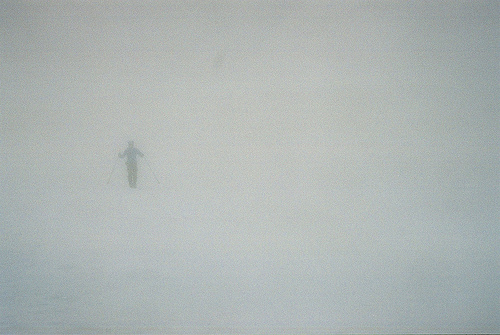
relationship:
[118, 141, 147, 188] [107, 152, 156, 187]
man holding ski poles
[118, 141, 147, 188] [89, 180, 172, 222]
man standing in snow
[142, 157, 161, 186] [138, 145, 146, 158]
pole in hand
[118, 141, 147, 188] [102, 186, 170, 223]
man standing in snow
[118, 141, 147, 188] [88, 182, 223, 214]
man standing in snow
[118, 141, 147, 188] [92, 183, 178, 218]
man standing in snow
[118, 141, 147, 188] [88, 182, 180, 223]
man standing in snow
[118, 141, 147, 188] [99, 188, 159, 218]
man standing in snow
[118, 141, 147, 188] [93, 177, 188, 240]
man standing in snow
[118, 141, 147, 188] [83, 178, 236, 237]
man standing in snow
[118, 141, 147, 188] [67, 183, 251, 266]
man standing in snow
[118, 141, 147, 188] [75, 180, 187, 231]
man on snow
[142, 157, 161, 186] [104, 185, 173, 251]
pole sticking in snow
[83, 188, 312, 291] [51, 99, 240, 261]
snow on ground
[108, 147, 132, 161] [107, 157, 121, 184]
hand holding pole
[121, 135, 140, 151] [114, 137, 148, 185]
head of man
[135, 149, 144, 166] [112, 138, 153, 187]
arm of man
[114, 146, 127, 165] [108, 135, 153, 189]
arm of man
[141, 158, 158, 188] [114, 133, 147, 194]
stick of man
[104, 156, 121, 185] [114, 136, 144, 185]
stick of man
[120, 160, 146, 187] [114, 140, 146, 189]
legs of man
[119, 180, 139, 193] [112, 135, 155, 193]
shoes of man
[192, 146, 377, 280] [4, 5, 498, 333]
patch of snow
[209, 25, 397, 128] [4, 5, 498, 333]
flurry of snow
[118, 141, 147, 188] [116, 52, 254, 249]
man in field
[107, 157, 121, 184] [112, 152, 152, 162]
pole in hand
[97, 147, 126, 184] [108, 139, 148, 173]
pole in hand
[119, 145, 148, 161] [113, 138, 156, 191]
jacket on person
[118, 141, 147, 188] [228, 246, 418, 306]
man through snow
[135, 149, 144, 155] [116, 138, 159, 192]
arm of person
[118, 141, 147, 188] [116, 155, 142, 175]
man wearing outfit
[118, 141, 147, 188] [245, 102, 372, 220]
man standing mist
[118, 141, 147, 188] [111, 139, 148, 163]
man with arms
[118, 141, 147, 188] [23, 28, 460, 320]
man on scene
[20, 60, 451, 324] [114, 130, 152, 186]
picture with person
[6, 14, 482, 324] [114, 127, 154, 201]
image with person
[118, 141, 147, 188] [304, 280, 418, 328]
man on snow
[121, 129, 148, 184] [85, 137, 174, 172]
man holds poles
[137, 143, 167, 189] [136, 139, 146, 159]
pole on hand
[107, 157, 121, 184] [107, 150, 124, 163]
pole on hand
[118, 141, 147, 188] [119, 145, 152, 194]
man wears clothes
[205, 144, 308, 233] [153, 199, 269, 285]
field covered with snow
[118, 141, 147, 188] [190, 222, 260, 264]
man walking snow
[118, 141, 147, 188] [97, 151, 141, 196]
man holding poles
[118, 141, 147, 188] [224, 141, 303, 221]
man obscured fog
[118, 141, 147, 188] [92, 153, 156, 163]
man holding poles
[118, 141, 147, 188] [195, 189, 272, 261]
man in fog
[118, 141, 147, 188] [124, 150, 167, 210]
man in clothes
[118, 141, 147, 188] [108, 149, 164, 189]
man in clothes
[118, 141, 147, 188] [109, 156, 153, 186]
man holding poles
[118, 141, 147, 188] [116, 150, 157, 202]
man in clothes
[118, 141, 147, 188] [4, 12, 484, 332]
man in field